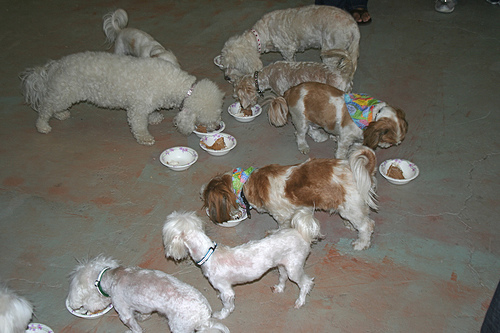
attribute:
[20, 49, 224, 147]
pet — white, eating, toy poodle, chowing down, standing, curly haired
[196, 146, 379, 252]
pet — eating, brown, white, standing, chowing down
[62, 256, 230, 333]
pet — eating, chowing down, white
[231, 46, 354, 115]
pet — eating, velvety, tiny, chowing down, standing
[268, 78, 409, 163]
pet — chowing down, brown, white, eating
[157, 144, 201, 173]
dish — white, empty, china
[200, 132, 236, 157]
dish — china, white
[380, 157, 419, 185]
dish — white, china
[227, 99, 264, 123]
dish — white, china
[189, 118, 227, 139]
dish — white, china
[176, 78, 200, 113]
collar — metallic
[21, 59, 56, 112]
tail — fluffy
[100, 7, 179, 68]
pet — tiny, eating, white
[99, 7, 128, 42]
tail — curled, fluffy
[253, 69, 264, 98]
collar — black, studded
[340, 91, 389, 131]
scarf — multi-colored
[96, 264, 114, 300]
collar — white, green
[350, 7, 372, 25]
sandal — black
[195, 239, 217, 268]
collar — white, black, blue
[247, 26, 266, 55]
collar — white with red spots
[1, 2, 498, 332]
floor — slate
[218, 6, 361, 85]
pet — white, eating, standing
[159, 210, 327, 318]
pet — white, standing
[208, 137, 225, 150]
food — brown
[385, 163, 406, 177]
food — brown